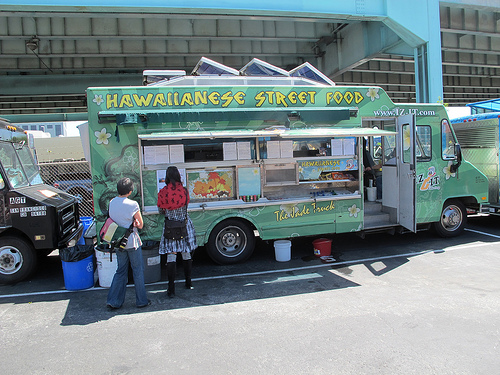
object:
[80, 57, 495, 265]
food truck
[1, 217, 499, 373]
street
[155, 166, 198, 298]
woman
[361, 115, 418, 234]
door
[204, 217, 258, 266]
rear wheel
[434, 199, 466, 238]
front wheel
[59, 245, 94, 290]
garbage can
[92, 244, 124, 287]
garbage can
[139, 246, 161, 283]
garbage can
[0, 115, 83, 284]
truck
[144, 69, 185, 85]
solar panel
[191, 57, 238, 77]
solar panel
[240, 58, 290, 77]
solar panel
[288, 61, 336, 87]
solar panel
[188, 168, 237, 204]
service window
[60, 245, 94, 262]
trash bag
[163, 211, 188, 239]
bag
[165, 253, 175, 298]
back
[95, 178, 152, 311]
woman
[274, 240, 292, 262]
bucket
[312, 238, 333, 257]
bucket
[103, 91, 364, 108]
text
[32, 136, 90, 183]
building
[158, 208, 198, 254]
skirt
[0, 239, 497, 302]
stripe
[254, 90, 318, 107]
street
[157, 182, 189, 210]
sweater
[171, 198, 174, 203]
dot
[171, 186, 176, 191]
dot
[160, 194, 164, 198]
dot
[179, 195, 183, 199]
dot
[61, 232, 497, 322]
shadow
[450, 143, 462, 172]
side mirror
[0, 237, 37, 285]
tire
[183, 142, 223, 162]
window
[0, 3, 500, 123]
bridge